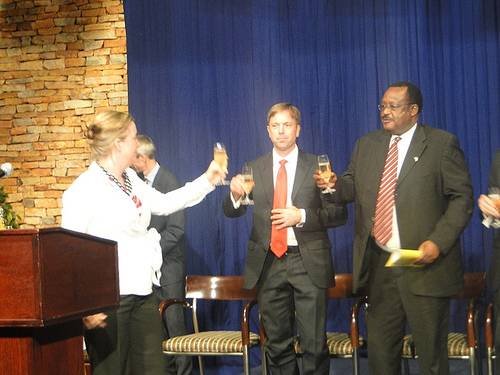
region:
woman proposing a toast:
[60, 110, 226, 372]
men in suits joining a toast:
[220, 77, 475, 372]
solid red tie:
[270, 152, 291, 259]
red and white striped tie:
[362, 136, 402, 244]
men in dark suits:
[227, 80, 470, 372]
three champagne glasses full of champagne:
[205, 141, 335, 204]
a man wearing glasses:
[372, 80, 422, 135]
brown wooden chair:
[145, 265, 270, 370]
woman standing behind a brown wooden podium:
[0, 95, 232, 370]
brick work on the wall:
[2, 0, 124, 227]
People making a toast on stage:
[57, 75, 497, 373]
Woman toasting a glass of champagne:
[57, 109, 227, 371]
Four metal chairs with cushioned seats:
[152, 269, 497, 374]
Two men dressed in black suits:
[222, 79, 474, 374]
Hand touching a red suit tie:
[262, 155, 300, 259]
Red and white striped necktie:
[372, 134, 401, 249]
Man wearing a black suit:
[222, 99, 347, 374]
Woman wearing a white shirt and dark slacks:
[53, 110, 228, 374]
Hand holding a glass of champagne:
[475, 184, 498, 234]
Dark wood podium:
[0, 225, 121, 373]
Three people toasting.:
[61, 78, 476, 350]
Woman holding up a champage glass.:
[59, 107, 230, 286]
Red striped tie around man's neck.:
[372, 134, 401, 247]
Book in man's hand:
[383, 244, 438, 269]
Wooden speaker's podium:
[0, 224, 120, 374]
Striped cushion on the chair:
[165, 327, 258, 354]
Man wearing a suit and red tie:
[226, 105, 347, 372]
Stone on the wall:
[3, 52, 129, 226]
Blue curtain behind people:
[128, 50, 499, 372]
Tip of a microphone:
[0, 157, 10, 177]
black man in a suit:
[313, 80, 465, 374]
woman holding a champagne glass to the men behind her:
[60, 110, 230, 374]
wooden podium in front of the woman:
[0, 225, 122, 373]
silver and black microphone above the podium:
[0, 162, 12, 179]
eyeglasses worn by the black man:
[376, 101, 413, 111]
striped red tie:
[374, 135, 399, 245]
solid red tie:
[271, 157, 289, 257]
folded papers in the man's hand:
[383, 246, 427, 269]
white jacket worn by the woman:
[58, 166, 216, 296]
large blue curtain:
[126, 47, 496, 370]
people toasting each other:
[81, 82, 483, 342]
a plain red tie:
[266, 158, 321, 281]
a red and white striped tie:
[379, 144, 418, 259]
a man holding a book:
[374, 227, 456, 288]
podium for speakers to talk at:
[12, 194, 134, 355]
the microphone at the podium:
[5, 147, 27, 240]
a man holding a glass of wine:
[236, 127, 365, 352]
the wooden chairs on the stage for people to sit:
[175, 262, 472, 365]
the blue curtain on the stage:
[127, 4, 459, 224]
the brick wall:
[5, 12, 145, 193]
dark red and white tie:
[373, 140, 397, 245]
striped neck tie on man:
[373, 141, 397, 242]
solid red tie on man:
[270, 160, 289, 257]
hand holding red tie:
[266, 202, 304, 228]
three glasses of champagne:
[195, 138, 357, 220]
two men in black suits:
[226, 78, 475, 368]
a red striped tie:
[370, 122, 407, 267]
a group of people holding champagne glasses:
[40, 64, 481, 350]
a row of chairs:
[162, 238, 491, 369]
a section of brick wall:
[8, 13, 112, 95]